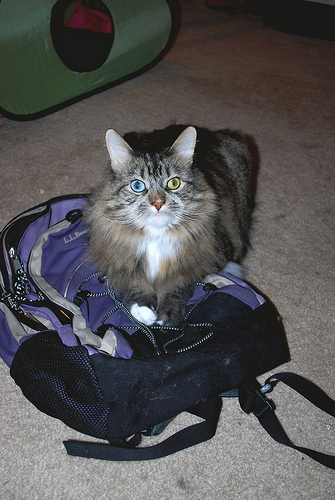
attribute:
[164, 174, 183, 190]
yelloweye — yellow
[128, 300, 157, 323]
paw — white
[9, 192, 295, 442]
backpack — blue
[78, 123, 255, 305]
gray cat — grey, white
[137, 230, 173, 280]
chest — white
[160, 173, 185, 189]
eye — brown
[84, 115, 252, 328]
cat — furry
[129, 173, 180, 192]
eyes — mismatched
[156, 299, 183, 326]
grey paw — gray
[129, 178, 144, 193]
eye — blue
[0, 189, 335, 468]
backpack — black, purple